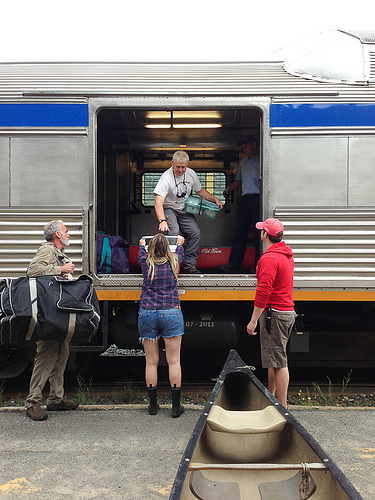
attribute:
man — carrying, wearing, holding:
[8, 196, 113, 451]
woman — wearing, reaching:
[127, 210, 206, 401]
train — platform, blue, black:
[2, 23, 370, 362]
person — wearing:
[90, 199, 210, 457]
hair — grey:
[43, 217, 65, 247]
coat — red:
[250, 249, 317, 323]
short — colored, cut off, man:
[249, 311, 311, 384]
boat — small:
[196, 388, 309, 493]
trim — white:
[176, 234, 190, 260]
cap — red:
[262, 206, 283, 243]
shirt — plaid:
[156, 268, 188, 304]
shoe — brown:
[19, 393, 89, 429]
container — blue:
[145, 221, 189, 266]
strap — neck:
[158, 172, 219, 239]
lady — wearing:
[121, 223, 216, 403]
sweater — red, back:
[267, 240, 307, 303]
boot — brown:
[134, 369, 218, 456]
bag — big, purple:
[2, 232, 114, 349]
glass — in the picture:
[166, 173, 198, 209]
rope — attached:
[257, 442, 316, 493]